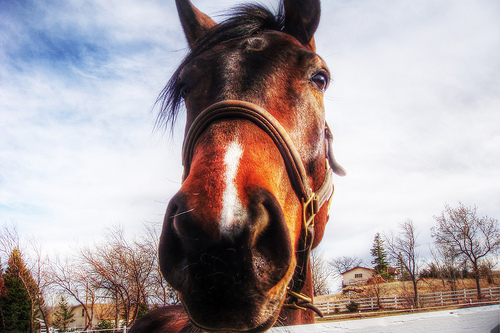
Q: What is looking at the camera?
A: A horse.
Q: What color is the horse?
A: Red and white.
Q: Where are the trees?
A: Behind the horse.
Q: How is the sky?
A: Cloudy.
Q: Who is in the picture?
A: No one.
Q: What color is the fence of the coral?
A: White.